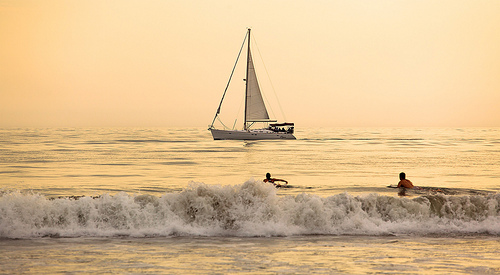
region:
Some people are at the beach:
[11, 15, 486, 265]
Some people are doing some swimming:
[20, 15, 475, 246]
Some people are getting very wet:
[41, 11, 468, 246]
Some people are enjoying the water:
[16, 13, 476, 273]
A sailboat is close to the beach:
[33, 6, 435, 241]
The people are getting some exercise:
[21, 12, 492, 262]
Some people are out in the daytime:
[23, 23, 478, 269]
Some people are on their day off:
[25, 7, 473, 267]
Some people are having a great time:
[30, 15, 475, 256]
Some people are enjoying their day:
[25, 20, 482, 256]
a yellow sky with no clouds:
[19, 45, 77, 89]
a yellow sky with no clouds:
[100, 66, 154, 120]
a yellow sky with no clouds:
[335, 63, 380, 108]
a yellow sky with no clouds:
[373, 51, 415, 93]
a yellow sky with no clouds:
[456, 29, 490, 70]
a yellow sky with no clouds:
[459, 99, 497, 136]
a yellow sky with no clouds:
[52, 82, 103, 132]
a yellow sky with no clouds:
[16, 98, 71, 136]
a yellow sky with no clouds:
[39, 75, 77, 96]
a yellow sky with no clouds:
[47, 21, 78, 39]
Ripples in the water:
[2, 204, 47, 240]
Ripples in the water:
[63, 192, 110, 229]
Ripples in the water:
[138, 225, 182, 262]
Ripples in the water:
[189, 231, 241, 270]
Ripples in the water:
[250, 229, 304, 256]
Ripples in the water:
[312, 232, 345, 252]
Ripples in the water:
[301, 245, 352, 268]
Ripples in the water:
[345, 230, 401, 270]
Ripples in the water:
[391, 232, 428, 252]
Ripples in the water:
[420, 240, 470, 264]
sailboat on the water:
[194, 32, 320, 146]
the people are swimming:
[246, 163, 426, 205]